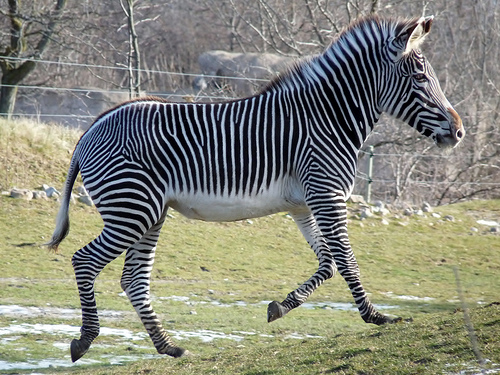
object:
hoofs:
[70, 339, 90, 363]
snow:
[165, 329, 244, 344]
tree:
[2, 0, 67, 119]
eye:
[412, 74, 427, 80]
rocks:
[431, 211, 441, 218]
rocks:
[420, 200, 431, 211]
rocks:
[378, 217, 388, 226]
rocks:
[359, 207, 373, 218]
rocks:
[370, 201, 383, 213]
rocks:
[444, 215, 455, 223]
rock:
[37, 89, 121, 130]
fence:
[0, 56, 500, 209]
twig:
[433, 252, 493, 373]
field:
[0, 116, 497, 373]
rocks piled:
[349, 192, 417, 236]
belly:
[164, 180, 293, 224]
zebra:
[45, 15, 466, 363]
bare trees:
[11, 11, 211, 67]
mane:
[262, 15, 410, 92]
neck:
[275, 53, 388, 145]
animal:
[191, 49, 285, 98]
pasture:
[2, 120, 496, 372]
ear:
[389, 17, 426, 54]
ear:
[416, 15, 434, 46]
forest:
[3, 2, 484, 372]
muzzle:
[431, 109, 465, 151]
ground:
[4, 100, 484, 373]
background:
[6, 2, 497, 143]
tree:
[251, 1, 277, 51]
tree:
[129, 0, 144, 99]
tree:
[363, 0, 500, 220]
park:
[2, 1, 498, 370]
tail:
[44, 152, 79, 254]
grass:
[2, 117, 499, 373]